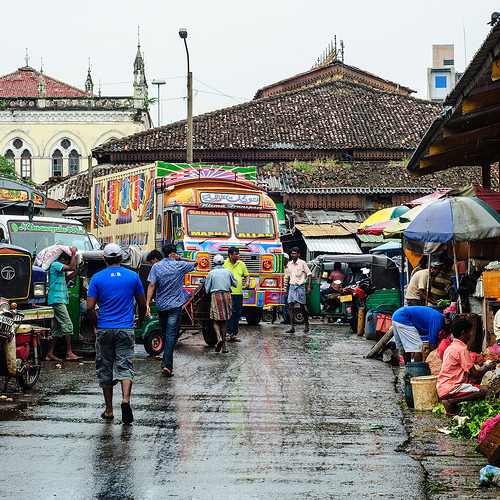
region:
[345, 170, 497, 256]
umbrellas used to cover merchandise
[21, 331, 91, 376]
man is barefoot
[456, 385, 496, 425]
lettuce next to the child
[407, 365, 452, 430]
white bucket next to child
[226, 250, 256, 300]
man has a yellow shirt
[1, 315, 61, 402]
scooter parked in front of vehicle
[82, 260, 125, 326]
man is wearing a blue shirt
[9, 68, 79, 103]
roof is red on the building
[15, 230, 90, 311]
man is carrying a bag on his shoulder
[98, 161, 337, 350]
truck is multi-colored with pictures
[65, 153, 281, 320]
the truck in the road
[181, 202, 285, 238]
the windshield of the truck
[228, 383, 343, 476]
the road is wet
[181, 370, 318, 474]
the road is slippery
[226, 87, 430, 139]
the shingles on the roof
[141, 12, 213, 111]
the street light above the truck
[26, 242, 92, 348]
the man carrying the sack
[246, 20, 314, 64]
the sky is gray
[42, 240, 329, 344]
people on the road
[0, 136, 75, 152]
the arches over the windows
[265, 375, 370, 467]
the road is slippery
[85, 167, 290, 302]
the truck on the road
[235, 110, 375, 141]
the shingles on the roof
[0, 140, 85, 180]
the arches over the windows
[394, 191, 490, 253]
the blue and white umbrella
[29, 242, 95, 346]
man carrying a sack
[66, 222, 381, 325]
people in the street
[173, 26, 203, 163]
A street light lamp post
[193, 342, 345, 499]
A piece of wet road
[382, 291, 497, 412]
People working on the side of a road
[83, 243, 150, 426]
A man in a blue shirt walking down the street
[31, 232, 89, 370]
A barefooted man carrying a bag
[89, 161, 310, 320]
A big colorful bus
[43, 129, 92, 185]
An arched window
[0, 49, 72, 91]
The top roof of a build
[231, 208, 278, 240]
Windshield of a bus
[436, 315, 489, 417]
A young boy in red shorts with a white stripe down the side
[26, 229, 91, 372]
man carrying blanket overhead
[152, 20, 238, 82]
street light over road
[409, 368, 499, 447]
discarded vegetables from market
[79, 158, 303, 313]
elaborately painted box truck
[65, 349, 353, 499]
rain soaked pavement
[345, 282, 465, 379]
man working at stand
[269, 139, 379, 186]
grass growing on roof top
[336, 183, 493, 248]
umbrellas due to rain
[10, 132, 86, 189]
tall stained glass windows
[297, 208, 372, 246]
patches on roof tops